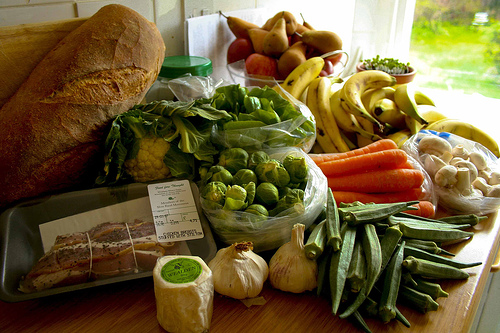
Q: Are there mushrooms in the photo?
A: Yes, there are mushrooms.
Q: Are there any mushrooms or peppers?
A: Yes, there are mushrooms.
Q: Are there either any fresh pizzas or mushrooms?
A: Yes, there are fresh mushrooms.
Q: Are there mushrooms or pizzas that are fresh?
A: Yes, the mushrooms are fresh.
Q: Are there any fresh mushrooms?
A: Yes, there are fresh mushrooms.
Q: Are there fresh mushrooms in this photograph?
A: Yes, there are fresh mushrooms.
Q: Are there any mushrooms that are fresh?
A: Yes, there are fresh mushrooms.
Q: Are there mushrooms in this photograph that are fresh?
A: Yes, there are mushrooms that are fresh.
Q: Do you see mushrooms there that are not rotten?
A: Yes, there are fresh mushrooms.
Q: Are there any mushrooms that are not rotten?
A: Yes, there are fresh mushrooms.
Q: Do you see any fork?
A: No, there are no forks.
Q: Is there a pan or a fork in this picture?
A: No, there are no forks or pans.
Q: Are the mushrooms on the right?
A: Yes, the mushrooms are on the right of the image.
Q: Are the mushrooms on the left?
A: No, the mushrooms are on the right of the image.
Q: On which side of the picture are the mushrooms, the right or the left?
A: The mushrooms are on the right of the image.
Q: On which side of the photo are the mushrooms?
A: The mushrooms are on the right of the image.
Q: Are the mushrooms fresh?
A: Yes, the mushrooms are fresh.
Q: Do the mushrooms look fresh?
A: Yes, the mushrooms are fresh.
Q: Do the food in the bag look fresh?
A: Yes, the mushrooms are fresh.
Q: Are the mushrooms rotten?
A: No, the mushrooms are fresh.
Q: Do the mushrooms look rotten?
A: No, the mushrooms are fresh.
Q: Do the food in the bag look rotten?
A: No, the mushrooms are fresh.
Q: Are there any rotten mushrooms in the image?
A: No, there are mushrooms but they are fresh.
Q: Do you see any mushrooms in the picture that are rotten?
A: No, there are mushrooms but they are fresh.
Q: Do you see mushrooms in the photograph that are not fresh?
A: No, there are mushrooms but they are fresh.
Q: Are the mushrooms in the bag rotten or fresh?
A: The mushrooms are fresh.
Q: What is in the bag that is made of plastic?
A: The mushrooms are in the bag.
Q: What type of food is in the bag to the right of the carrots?
A: The food is mushrooms.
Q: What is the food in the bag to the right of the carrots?
A: The food is mushrooms.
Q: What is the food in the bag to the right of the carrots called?
A: The food is mushrooms.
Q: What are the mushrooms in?
A: The mushrooms are in the bag.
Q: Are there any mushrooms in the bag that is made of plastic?
A: Yes, there are mushrooms in the bag.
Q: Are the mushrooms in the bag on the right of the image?
A: Yes, the mushrooms are in the bag.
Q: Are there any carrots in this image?
A: Yes, there are carrots.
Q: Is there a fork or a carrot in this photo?
A: Yes, there are carrots.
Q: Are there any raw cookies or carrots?
A: Yes, there are raw carrots.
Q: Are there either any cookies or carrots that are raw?
A: Yes, the carrots are raw.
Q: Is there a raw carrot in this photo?
A: Yes, there are raw carrots.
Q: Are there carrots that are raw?
A: Yes, there are carrots that are raw.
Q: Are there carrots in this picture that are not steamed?
A: Yes, there are raw carrots.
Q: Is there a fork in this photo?
A: No, there are no forks.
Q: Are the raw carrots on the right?
A: Yes, the carrots are on the right of the image.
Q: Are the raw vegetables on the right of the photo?
A: Yes, the carrots are on the right of the image.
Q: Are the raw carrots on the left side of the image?
A: No, the carrots are on the right of the image.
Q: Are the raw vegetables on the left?
A: No, the carrots are on the right of the image.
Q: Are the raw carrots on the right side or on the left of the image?
A: The carrots are on the right of the image.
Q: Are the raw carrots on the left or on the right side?
A: The carrots are on the right of the image.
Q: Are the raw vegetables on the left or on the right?
A: The carrots are on the right of the image.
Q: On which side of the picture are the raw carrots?
A: The carrots are on the right of the image.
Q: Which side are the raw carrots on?
A: The carrots are on the right of the image.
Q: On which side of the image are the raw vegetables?
A: The carrots are on the right of the image.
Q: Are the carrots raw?
A: Yes, the carrots are raw.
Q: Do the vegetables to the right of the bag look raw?
A: Yes, the carrots are raw.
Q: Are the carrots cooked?
A: No, the carrots are raw.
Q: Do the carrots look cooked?
A: No, the carrots are raw.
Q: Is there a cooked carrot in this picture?
A: No, there are carrots but they are raw.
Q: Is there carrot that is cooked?
A: No, there are carrots but they are raw.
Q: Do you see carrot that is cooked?
A: No, there are carrots but they are raw.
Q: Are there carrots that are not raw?
A: No, there are carrots but they are raw.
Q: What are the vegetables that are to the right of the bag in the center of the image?
A: The vegetables are carrots.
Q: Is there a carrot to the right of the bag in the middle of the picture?
A: Yes, there are carrots to the right of the bag.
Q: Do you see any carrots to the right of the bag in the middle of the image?
A: Yes, there are carrots to the right of the bag.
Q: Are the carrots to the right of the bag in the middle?
A: Yes, the carrots are to the right of the bag.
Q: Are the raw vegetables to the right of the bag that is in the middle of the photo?
A: Yes, the carrots are to the right of the bag.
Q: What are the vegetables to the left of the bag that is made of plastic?
A: The vegetables are carrots.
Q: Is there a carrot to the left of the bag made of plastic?
A: Yes, there are carrots to the left of the bag.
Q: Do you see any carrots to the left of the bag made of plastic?
A: Yes, there are carrots to the left of the bag.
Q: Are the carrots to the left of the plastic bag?
A: Yes, the carrots are to the left of the bag.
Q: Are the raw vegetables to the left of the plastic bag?
A: Yes, the carrots are to the left of the bag.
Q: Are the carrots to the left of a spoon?
A: No, the carrots are to the left of the bag.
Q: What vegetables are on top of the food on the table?
A: The vegetables are carrots.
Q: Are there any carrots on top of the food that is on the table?
A: Yes, there are carrots on top of the food.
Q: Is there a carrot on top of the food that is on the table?
A: Yes, there are carrots on top of the food.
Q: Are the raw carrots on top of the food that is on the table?
A: Yes, the carrots are on top of the food.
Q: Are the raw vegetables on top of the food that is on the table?
A: Yes, the carrots are on top of the food.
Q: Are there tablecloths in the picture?
A: No, there are no tablecloths.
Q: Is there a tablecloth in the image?
A: No, there are no tablecloths.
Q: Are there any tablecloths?
A: No, there are no tablecloths.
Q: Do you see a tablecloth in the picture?
A: No, there are no tablecloths.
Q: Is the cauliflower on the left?
A: Yes, the cauliflower is on the left of the image.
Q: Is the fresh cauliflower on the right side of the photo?
A: No, the cauliflower is on the left of the image.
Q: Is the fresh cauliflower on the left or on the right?
A: The cauliflower is on the left of the image.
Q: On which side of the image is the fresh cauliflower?
A: The cauliflower is on the left of the image.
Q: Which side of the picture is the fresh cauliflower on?
A: The cauliflower is on the left of the image.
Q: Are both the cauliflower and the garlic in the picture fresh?
A: Yes, both the cauliflower and the garlic are fresh.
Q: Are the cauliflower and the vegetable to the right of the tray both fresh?
A: Yes, both the cauliflower and the garlic are fresh.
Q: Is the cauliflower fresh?
A: Yes, the cauliflower is fresh.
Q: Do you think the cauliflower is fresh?
A: Yes, the cauliflower is fresh.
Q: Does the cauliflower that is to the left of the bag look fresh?
A: Yes, the cauliflower is fresh.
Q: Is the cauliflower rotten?
A: No, the cauliflower is fresh.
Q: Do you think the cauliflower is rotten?
A: No, the cauliflower is fresh.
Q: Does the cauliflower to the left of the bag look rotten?
A: No, the cauliflower is fresh.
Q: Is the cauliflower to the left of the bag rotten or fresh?
A: The cauliflower is fresh.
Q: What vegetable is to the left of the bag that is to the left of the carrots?
A: The vegetable is cauliflower.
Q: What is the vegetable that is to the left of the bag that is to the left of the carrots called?
A: The vegetable is cauliflower.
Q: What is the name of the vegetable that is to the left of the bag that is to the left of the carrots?
A: The vegetable is cauliflower.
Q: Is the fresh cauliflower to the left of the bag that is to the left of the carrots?
A: Yes, the cauliflower is to the left of the bag.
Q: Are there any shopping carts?
A: No, there are no shopping carts.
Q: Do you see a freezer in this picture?
A: No, there are no refrigerators.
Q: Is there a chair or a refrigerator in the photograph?
A: No, there are no refrigerators or chairs.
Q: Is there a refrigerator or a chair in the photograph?
A: No, there are no refrigerators or chairs.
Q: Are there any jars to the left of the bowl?
A: Yes, there is a jar to the left of the bowl.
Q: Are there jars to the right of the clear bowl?
A: No, the jar is to the left of the bowl.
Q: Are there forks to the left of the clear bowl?
A: No, there is a jar to the left of the bowl.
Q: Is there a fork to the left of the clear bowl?
A: No, there is a jar to the left of the bowl.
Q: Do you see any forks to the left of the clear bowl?
A: No, there is a jar to the left of the bowl.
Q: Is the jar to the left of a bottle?
A: No, the jar is to the left of the bowl.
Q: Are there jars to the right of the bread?
A: Yes, there is a jar to the right of the bread.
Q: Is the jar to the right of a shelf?
A: No, the jar is to the right of a bread.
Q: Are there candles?
A: No, there are no candles.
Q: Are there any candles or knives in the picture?
A: No, there are no candles or knives.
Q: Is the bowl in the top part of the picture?
A: Yes, the bowl is in the top of the image.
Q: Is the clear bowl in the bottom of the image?
A: No, the bowl is in the top of the image.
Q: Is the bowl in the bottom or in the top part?
A: The bowl is in the top of the image.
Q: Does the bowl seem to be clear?
A: Yes, the bowl is clear.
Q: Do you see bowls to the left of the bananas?
A: Yes, there is a bowl to the left of the bananas.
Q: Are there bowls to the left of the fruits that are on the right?
A: Yes, there is a bowl to the left of the bananas.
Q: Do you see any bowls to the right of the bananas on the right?
A: No, the bowl is to the left of the bananas.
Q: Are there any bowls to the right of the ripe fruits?
A: No, the bowl is to the left of the bananas.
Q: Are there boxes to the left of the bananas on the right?
A: No, there is a bowl to the left of the bananas.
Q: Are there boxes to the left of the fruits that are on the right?
A: No, there is a bowl to the left of the bananas.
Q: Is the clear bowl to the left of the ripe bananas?
A: Yes, the bowl is to the left of the bananas.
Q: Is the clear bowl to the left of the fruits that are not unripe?
A: Yes, the bowl is to the left of the bananas.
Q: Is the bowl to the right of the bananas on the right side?
A: No, the bowl is to the left of the bananas.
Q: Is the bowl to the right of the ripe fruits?
A: No, the bowl is to the left of the bananas.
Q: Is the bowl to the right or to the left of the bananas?
A: The bowl is to the left of the bananas.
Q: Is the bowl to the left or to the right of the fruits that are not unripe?
A: The bowl is to the left of the bananas.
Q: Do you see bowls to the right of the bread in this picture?
A: Yes, there is a bowl to the right of the bread.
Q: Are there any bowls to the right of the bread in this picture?
A: Yes, there is a bowl to the right of the bread.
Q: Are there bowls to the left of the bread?
A: No, the bowl is to the right of the bread.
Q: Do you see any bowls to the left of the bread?
A: No, the bowl is to the right of the bread.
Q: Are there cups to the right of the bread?
A: No, there is a bowl to the right of the bread.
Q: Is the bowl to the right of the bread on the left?
A: Yes, the bowl is to the right of the bread.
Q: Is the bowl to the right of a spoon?
A: No, the bowl is to the right of the bread.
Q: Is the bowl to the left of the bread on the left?
A: No, the bowl is to the right of the bread.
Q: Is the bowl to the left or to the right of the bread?
A: The bowl is to the right of the bread.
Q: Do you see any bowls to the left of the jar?
A: No, the bowl is to the right of the jar.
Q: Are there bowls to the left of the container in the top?
A: No, the bowl is to the right of the jar.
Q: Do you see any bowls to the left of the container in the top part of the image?
A: No, the bowl is to the right of the jar.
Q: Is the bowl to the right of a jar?
A: Yes, the bowl is to the right of a jar.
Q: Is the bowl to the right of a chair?
A: No, the bowl is to the right of a jar.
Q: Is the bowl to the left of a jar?
A: No, the bowl is to the right of a jar.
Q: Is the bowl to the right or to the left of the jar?
A: The bowl is to the right of the jar.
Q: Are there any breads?
A: Yes, there is a bread.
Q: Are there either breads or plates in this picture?
A: Yes, there is a bread.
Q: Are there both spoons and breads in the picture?
A: No, there is a bread but no spoons.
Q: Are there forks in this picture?
A: No, there are no forks.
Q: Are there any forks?
A: No, there are no forks.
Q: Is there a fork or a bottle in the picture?
A: No, there are no forks or bottles.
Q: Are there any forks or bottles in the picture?
A: No, there are no forks or bottles.